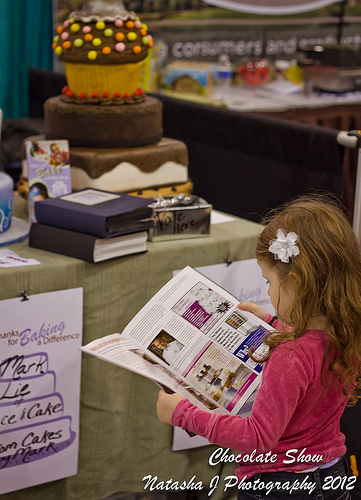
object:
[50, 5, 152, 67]
frosting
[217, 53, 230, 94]
bottle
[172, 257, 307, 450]
sign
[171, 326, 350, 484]
shirt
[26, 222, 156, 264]
books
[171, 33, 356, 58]
sign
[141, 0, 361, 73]
window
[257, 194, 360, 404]
hair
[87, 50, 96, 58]
sprinkles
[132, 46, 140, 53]
sprinkles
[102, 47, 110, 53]
sprinkles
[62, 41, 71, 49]
sprinkles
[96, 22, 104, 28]
sprinkles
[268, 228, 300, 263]
flower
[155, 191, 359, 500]
girl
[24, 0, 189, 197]
cake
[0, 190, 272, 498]
table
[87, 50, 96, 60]
ball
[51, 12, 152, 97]
cupcake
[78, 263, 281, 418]
brochure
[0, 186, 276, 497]
table cloth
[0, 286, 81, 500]
sign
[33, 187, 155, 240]
books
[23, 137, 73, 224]
brochure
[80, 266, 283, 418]
magazine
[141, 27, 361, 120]
table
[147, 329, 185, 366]
man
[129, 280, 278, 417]
picture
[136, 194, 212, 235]
ballot box